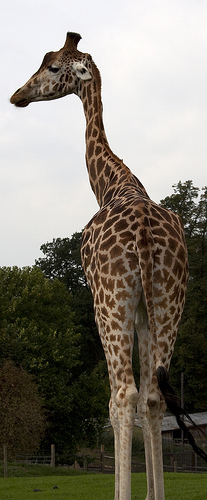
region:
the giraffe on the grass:
[5, 20, 181, 491]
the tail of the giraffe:
[131, 219, 165, 377]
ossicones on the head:
[57, 27, 94, 50]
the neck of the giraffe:
[67, 77, 140, 200]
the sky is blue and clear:
[102, 24, 187, 168]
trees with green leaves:
[9, 251, 90, 374]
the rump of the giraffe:
[103, 197, 188, 282]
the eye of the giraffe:
[45, 61, 63, 80]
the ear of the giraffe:
[67, 59, 93, 81]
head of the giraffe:
[18, 26, 112, 121]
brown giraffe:
[11, 27, 193, 482]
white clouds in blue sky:
[34, 181, 49, 200]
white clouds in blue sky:
[37, 194, 60, 228]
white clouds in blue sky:
[7, 202, 29, 237]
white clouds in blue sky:
[143, 125, 167, 166]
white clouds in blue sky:
[13, 145, 44, 164]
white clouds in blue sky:
[32, 118, 55, 151]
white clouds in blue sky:
[111, 95, 122, 111]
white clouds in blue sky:
[132, 84, 158, 110]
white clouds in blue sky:
[138, 95, 163, 118]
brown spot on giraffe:
[42, 86, 51, 92]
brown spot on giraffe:
[51, 83, 57, 90]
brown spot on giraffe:
[87, 108, 92, 118]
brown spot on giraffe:
[86, 118, 92, 137]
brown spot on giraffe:
[94, 146, 101, 154]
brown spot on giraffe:
[89, 158, 96, 179]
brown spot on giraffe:
[96, 156, 104, 175]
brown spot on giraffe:
[100, 235, 115, 251]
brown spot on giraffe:
[139, 228, 147, 236]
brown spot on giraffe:
[164, 275, 173, 293]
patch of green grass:
[60, 477, 108, 497]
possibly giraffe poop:
[30, 483, 60, 491]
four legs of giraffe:
[108, 413, 165, 498]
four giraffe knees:
[106, 386, 165, 416]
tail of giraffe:
[134, 223, 178, 403]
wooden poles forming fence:
[1, 445, 55, 465]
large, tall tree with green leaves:
[0, 266, 83, 361]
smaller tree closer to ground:
[0, 357, 47, 462]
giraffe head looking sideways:
[7, 30, 99, 108]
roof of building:
[165, 417, 174, 429]